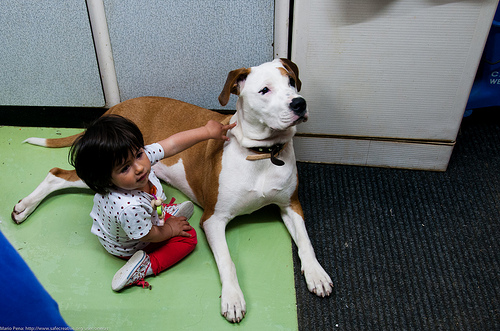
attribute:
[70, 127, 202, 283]
child — petting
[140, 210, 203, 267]
pants — red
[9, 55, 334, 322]
dog — large , brown and white, brown, white, reclined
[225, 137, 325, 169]
collar — brown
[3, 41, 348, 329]
pitt bull — large 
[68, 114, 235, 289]
toddler — petting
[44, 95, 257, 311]
toddler — polka dot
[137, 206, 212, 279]
pants — red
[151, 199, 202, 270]
pants — red